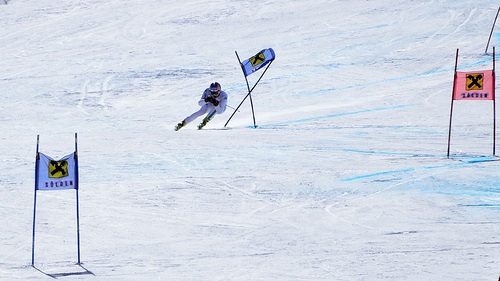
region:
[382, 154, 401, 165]
part of an ice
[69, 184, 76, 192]
part of a post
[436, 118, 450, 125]
edge of a post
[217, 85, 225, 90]
part of an helmet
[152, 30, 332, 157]
a skier rounding the blue flag on snow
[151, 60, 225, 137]
skier rounding the blue flag on snow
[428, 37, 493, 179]
pink boundary flag in the snow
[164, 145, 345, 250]
ski tracks in the snow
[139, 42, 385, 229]
a skier rounding the blue flag on snow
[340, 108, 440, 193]
light blue lines in the snow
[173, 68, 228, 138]
skier with his ski outfit on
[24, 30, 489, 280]
a skier rounding the blue flag on snow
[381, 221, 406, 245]
part of the snow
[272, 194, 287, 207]
part of a hill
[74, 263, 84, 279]
part of a shadow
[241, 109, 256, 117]
edge of a sign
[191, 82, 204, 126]
part of a knee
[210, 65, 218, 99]
part of an helmet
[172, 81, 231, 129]
the skier is goind down a hill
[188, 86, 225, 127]
the skier is wearing an outfit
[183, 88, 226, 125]
the outfit is blue in color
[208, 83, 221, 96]
the skier is wearing a helmet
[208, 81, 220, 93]
the helmet is made of plastic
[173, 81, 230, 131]
the skier is at an angle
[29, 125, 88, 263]
a marker is on the snow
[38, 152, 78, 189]
a sign is in the snow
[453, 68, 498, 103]
the sign is red in color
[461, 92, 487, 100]
the sign has lettering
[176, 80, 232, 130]
a person skiing down the hill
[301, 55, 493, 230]
a blue line all over the snow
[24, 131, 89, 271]
two blue poles holding up a blue flag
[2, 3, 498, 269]
the snow all over the ground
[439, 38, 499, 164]
a pink flag stuck on the poles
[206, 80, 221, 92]
a helmet on the person's head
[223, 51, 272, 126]
a blue flag stuck on bent poles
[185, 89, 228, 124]
the white outfit the person is wearing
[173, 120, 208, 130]
the skiis on the person's feet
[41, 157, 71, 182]
a logo on the flag